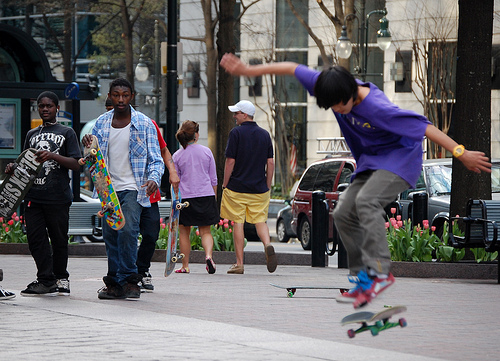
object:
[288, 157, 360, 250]
minivan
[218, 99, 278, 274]
man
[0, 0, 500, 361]
picture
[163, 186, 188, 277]
skating board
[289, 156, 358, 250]
car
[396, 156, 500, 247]
car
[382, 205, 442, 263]
flowers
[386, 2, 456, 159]
tree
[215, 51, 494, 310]
boy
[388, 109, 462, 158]
arm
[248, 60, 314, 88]
arm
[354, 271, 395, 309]
sneaker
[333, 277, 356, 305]
sneaker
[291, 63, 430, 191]
tee shirt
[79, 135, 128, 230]
skate board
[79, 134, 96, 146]
hand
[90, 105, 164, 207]
plaid shirt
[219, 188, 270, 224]
yellow shorts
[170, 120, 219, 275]
girl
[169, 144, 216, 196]
purple shirt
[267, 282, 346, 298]
skate board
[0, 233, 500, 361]
side walk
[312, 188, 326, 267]
metal pole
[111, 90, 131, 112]
admiring look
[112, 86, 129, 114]
face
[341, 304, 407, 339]
board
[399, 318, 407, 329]
wheels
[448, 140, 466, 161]
watch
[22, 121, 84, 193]
t-shirt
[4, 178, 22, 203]
stickers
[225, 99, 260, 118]
cap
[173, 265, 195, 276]
shoes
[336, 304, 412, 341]
skateboard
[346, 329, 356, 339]
wheels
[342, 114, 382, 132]
logo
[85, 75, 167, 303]
boy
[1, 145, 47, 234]
skateboard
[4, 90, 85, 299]
boy